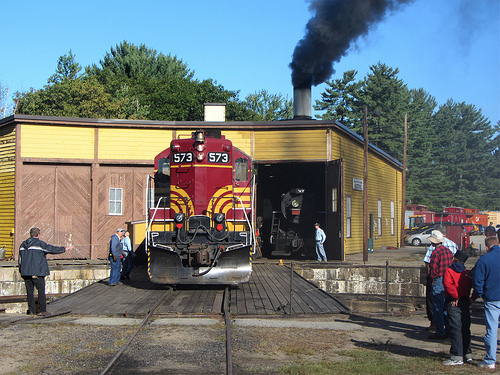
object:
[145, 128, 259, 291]
train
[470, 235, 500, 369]
man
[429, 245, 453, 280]
shirt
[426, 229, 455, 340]
man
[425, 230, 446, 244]
hat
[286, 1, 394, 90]
smoke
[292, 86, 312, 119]
stack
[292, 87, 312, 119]
smoke stack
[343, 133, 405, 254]
siding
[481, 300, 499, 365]
jeans